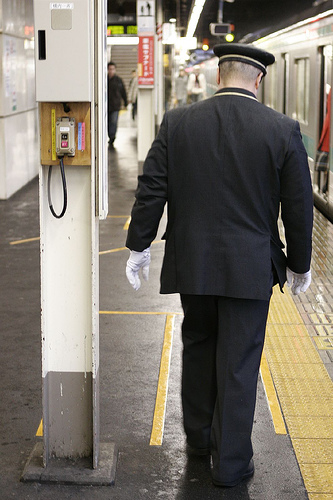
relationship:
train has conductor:
[187, 5, 332, 223] [124, 43, 315, 486]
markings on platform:
[6, 208, 293, 450] [0, 112, 332, 491]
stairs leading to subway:
[108, 38, 141, 109] [4, 0, 331, 495]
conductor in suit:
[124, 43, 315, 486] [114, 88, 332, 491]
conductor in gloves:
[124, 43, 315, 486] [124, 248, 310, 293]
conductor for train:
[124, 43, 315, 486] [187, 5, 332, 223]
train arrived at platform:
[187, 5, 332, 223] [0, 112, 332, 491]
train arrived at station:
[187, 5, 332, 223] [4, 0, 331, 495]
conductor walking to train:
[124, 43, 315, 486] [187, 5, 332, 223]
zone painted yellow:
[11, 206, 332, 486] [6, 213, 333, 499]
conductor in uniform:
[124, 40, 315, 491] [121, 39, 319, 490]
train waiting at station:
[187, 5, 332, 223] [4, 0, 331, 495]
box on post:
[39, 95, 92, 170] [15, 2, 123, 489]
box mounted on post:
[39, 95, 92, 170] [15, 2, 123, 489]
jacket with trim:
[113, 88, 317, 301] [210, 90, 261, 106]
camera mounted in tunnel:
[208, 1, 236, 40] [5, 4, 330, 498]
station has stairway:
[4, 0, 331, 495] [108, 38, 141, 109]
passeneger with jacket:
[315, 84, 332, 202] [315, 92, 333, 156]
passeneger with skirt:
[315, 84, 332, 202] [313, 153, 332, 173]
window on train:
[291, 61, 309, 121] [187, 5, 332, 223]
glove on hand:
[122, 247, 153, 292] [124, 249, 152, 291]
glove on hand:
[286, 269, 313, 297] [284, 267, 314, 296]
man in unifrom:
[124, 43, 315, 486] [120, 43, 318, 488]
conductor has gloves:
[124, 40, 315, 491] [124, 248, 310, 293]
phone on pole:
[45, 118, 85, 222] [15, 2, 123, 489]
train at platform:
[187, 5, 332, 223] [0, 112, 332, 491]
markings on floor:
[6, 208, 293, 450] [0, 112, 332, 491]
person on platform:
[108, 58, 131, 146] [0, 112, 332, 491]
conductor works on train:
[124, 40, 315, 491] [187, 5, 332, 223]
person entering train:
[108, 58, 131, 146] [187, 5, 332, 223]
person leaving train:
[108, 58, 131, 146] [187, 5, 332, 223]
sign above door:
[109, 23, 140, 36] [108, 33, 142, 48]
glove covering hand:
[122, 247, 153, 292] [124, 249, 152, 291]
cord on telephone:
[47, 154, 68, 219] [45, 118, 85, 222]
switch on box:
[59, 131, 69, 151] [39, 95, 92, 170]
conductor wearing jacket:
[124, 40, 315, 491] [113, 88, 317, 301]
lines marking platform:
[6, 208, 293, 450] [0, 112, 332, 491]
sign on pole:
[135, 31, 162, 93] [134, 0, 159, 181]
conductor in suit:
[124, 40, 315, 491] [114, 88, 332, 491]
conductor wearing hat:
[124, 40, 315, 491] [209, 40, 275, 78]